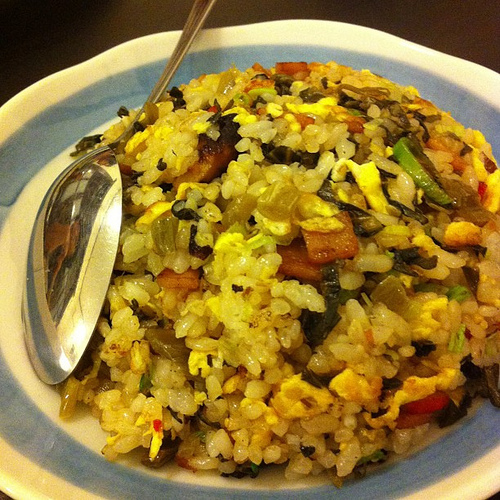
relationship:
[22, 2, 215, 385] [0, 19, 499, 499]
spoon in bowl.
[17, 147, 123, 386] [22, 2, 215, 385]
reflection in spoon.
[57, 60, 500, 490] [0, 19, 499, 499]
rice in bowl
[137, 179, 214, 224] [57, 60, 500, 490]
cheese in rice.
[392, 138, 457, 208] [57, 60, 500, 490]
peppers in rice.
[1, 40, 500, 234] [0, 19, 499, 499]
stripe on bowl.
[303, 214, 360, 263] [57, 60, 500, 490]
brown in rice.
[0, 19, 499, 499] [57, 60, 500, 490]
bowl of food.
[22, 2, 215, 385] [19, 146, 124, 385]
spoon appears large.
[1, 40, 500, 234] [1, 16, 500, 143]
blue and white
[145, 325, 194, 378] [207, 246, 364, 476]
may contain grains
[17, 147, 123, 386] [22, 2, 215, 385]
reflections in spoon.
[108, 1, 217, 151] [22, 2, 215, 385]
handle of spoon.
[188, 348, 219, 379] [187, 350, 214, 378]
piece of egg.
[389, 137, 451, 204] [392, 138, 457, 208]
prieces of pepper.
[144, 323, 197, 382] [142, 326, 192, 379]
piece of onion.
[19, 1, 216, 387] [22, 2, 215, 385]
shiny silver spoon.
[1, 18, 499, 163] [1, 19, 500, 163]
wavey plate rim.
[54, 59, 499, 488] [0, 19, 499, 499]
meal on plate.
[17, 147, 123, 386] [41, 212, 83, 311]
reflection of person.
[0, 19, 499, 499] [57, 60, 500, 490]
plate of rice.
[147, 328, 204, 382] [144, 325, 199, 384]
chopped up onions.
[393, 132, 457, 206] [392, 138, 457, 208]
chopped up pepper.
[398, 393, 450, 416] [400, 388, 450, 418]
chopped up pepper.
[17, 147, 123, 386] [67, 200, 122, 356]
reflections of light.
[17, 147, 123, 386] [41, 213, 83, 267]
reflection of phone.